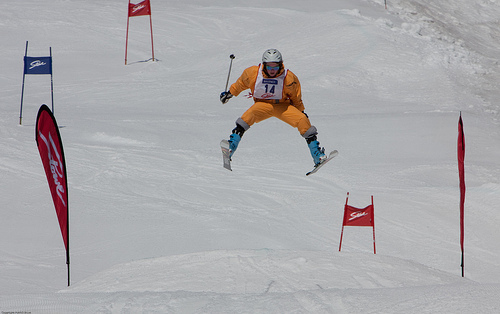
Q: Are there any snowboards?
A: No, there are no snowboards.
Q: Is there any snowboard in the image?
A: No, there are no snowboards.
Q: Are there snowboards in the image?
A: No, there are no snowboards.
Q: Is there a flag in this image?
A: Yes, there is a flag.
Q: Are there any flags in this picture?
A: Yes, there is a flag.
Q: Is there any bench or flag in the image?
A: Yes, there is a flag.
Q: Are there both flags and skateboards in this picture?
A: No, there is a flag but no skateboards.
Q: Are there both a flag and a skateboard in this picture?
A: No, there is a flag but no skateboards.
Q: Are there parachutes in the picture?
A: No, there are no parachutes.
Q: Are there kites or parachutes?
A: No, there are no parachutes or kites.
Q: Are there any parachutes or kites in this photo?
A: No, there are no parachutes or kites.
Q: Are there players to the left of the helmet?
A: No, there is a flag to the left of the helmet.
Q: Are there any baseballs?
A: No, there are no baseballs.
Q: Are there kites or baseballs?
A: No, there are no baseballs or kites.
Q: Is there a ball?
A: No, there are no balls.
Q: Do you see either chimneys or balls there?
A: No, there are no balls or chimneys.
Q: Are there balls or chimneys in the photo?
A: No, there are no balls or chimneys.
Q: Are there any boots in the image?
A: Yes, there are boots.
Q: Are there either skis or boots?
A: Yes, there are boots.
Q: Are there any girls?
A: No, there are no girls.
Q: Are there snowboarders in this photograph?
A: Yes, there is a snowboarder.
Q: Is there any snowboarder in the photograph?
A: Yes, there is a snowboarder.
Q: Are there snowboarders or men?
A: Yes, there is a snowboarder.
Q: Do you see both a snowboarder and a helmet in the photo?
A: Yes, there are both a snowboarder and a helmet.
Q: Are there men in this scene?
A: No, there are no men.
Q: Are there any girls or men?
A: No, there are no men or girls.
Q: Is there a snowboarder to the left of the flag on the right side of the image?
A: Yes, there is a snowboarder to the left of the flag.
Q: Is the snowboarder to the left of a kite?
A: No, the snowboarder is to the left of the flag.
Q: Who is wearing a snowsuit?
A: The snowboarder is wearing a snowsuit.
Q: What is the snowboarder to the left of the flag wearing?
A: The snowboarder is wearing a snow suit.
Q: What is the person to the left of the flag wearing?
A: The snowboarder is wearing a snow suit.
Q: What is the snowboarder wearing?
A: The snowboarder is wearing a snow suit.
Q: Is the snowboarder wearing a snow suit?
A: Yes, the snowboarder is wearing a snow suit.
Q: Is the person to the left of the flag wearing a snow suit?
A: Yes, the snowboarder is wearing a snow suit.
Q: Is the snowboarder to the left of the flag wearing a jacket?
A: No, the snowboarder is wearing a snow suit.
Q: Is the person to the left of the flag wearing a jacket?
A: No, the snowboarder is wearing a snow suit.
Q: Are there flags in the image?
A: Yes, there is a flag.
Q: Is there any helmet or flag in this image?
A: Yes, there is a flag.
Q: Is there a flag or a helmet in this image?
A: Yes, there is a flag.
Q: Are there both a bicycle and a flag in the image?
A: No, there is a flag but no bicycles.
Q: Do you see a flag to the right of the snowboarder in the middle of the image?
A: Yes, there is a flag to the right of the snowboarder.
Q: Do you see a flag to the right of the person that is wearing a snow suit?
A: Yes, there is a flag to the right of the snowboarder.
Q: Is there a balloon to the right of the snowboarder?
A: No, there is a flag to the right of the snowboarder.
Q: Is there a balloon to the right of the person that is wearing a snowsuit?
A: No, there is a flag to the right of the snowboarder.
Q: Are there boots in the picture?
A: Yes, there are boots.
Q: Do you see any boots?
A: Yes, there are boots.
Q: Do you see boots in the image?
A: Yes, there are boots.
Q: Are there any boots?
A: Yes, there are boots.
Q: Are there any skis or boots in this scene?
A: Yes, there are boots.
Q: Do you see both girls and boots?
A: No, there are boots but no girls.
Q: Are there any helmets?
A: Yes, there is a helmet.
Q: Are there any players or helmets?
A: Yes, there is a helmet.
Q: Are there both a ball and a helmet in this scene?
A: No, there is a helmet but no balls.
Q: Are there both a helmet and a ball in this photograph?
A: No, there is a helmet but no balls.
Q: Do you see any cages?
A: No, there are no cages.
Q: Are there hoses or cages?
A: No, there are no cages or hoses.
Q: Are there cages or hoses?
A: No, there are no cages or hoses.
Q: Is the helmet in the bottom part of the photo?
A: No, the helmet is in the top of the image.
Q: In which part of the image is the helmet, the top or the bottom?
A: The helmet is in the top of the image.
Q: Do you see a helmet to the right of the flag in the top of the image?
A: Yes, there is a helmet to the right of the flag.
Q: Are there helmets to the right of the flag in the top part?
A: Yes, there is a helmet to the right of the flag.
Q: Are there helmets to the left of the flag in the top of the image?
A: No, the helmet is to the right of the flag.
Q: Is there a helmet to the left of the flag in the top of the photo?
A: No, the helmet is to the right of the flag.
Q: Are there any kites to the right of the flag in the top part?
A: No, there is a helmet to the right of the flag.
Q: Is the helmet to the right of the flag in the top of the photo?
A: Yes, the helmet is to the right of the flag.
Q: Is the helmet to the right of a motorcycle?
A: No, the helmet is to the right of the flag.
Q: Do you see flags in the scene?
A: Yes, there is a flag.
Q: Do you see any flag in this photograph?
A: Yes, there is a flag.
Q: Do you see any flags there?
A: Yes, there is a flag.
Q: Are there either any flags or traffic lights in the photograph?
A: Yes, there is a flag.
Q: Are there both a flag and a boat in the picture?
A: No, there is a flag but no boats.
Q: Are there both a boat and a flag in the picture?
A: No, there is a flag but no boats.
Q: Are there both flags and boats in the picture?
A: No, there is a flag but no boats.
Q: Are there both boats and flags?
A: No, there is a flag but no boats.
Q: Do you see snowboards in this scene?
A: No, there are no snowboards.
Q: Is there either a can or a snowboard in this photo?
A: No, there are no snowboards or cans.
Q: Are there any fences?
A: No, there are no fences.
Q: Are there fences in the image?
A: No, there are no fences.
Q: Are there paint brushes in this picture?
A: No, there are no paint brushes.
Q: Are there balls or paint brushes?
A: No, there are no paint brushes or balls.